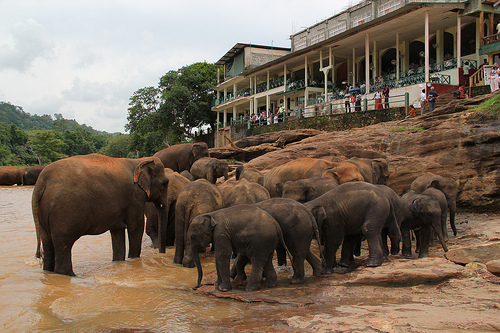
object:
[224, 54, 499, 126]
people watching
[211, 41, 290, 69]
roof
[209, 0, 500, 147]
building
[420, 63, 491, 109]
stairs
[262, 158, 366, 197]
elephant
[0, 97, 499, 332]
mud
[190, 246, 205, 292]
trunk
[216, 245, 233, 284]
legs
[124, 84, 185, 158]
trees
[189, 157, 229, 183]
elephant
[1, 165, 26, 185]
elephant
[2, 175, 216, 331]
water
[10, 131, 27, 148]
leaves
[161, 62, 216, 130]
trees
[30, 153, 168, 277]
elephant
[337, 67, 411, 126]
ground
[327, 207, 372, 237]
ground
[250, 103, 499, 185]
rocky background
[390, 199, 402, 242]
tail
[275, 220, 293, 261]
tail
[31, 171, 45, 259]
tail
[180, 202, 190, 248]
tail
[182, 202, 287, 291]
baby elephant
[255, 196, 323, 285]
baby elephant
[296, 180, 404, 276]
baby elephant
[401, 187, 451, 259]
baby elephant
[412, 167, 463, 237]
baby elephant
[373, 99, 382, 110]
skirt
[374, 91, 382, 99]
top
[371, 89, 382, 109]
person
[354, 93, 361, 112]
person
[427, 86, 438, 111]
person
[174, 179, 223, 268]
elephant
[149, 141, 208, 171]
elephant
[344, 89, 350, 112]
person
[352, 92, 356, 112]
person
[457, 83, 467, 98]
person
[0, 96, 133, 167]
mountain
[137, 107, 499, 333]
rocky area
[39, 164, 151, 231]
side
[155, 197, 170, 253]
trunk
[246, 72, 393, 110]
crowd